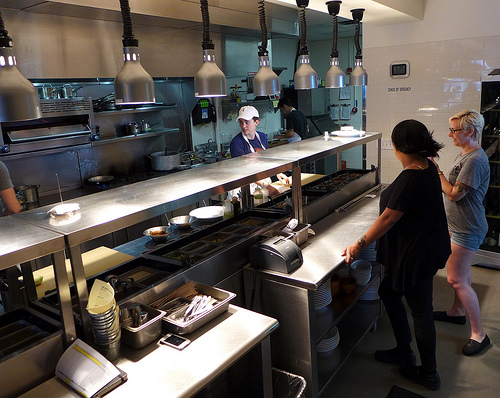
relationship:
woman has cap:
[229, 105, 291, 198] [235, 104, 259, 121]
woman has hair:
[341, 118, 453, 391] [391, 119, 445, 160]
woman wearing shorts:
[430, 108, 492, 358] [447, 227, 488, 251]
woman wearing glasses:
[430, 108, 492, 358] [447, 126, 466, 134]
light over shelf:
[114, 37, 156, 105] [0, 126, 384, 271]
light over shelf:
[193, 43, 229, 99] [0, 126, 384, 271]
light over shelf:
[253, 49, 280, 99] [0, 126, 384, 271]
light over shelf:
[293, 50, 319, 91] [0, 126, 384, 271]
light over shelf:
[324, 53, 347, 87] [0, 126, 384, 271]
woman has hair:
[430, 108, 492, 358] [447, 109, 485, 146]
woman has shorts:
[430, 108, 492, 358] [447, 227, 488, 251]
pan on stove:
[87, 172, 115, 185] [93, 162, 195, 187]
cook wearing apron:
[277, 96, 309, 145] [287, 129, 303, 145]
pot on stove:
[149, 151, 180, 171] [93, 162, 195, 187]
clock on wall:
[387, 61, 410, 78] [363, 1, 499, 192]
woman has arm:
[341, 118, 453, 391] [340, 178, 417, 265]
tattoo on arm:
[357, 233, 368, 251] [340, 178, 417, 265]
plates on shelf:
[312, 278, 333, 313] [244, 181, 412, 397]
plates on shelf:
[315, 325, 340, 354] [244, 181, 412, 397]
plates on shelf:
[357, 273, 380, 302] [244, 181, 412, 397]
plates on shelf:
[358, 233, 378, 261] [244, 181, 412, 397]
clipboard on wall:
[340, 104, 351, 122] [299, 35, 364, 170]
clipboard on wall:
[328, 103, 338, 122] [299, 35, 364, 170]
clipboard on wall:
[337, 83, 351, 103] [299, 35, 364, 170]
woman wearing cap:
[229, 105, 291, 198] [235, 104, 259, 121]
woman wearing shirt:
[430, 108, 492, 358] [442, 146, 491, 237]